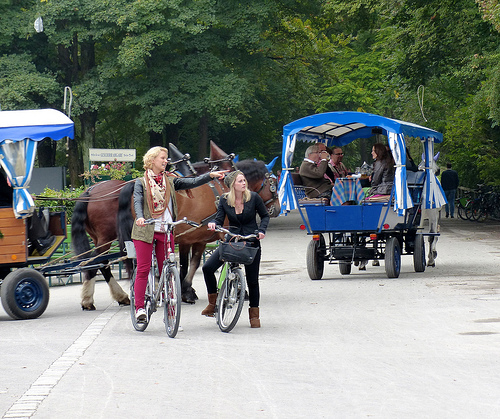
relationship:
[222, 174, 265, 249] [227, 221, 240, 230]
woman wearing black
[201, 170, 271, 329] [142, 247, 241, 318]
woman on bikes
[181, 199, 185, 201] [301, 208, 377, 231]
horse pulling carriage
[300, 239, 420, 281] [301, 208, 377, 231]
wheels of carriage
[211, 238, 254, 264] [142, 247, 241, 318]
basket on bikes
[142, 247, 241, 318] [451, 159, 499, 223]
bikes attached to railing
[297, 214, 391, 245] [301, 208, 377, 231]
reflectors on carriage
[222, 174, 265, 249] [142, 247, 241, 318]
woman on bikes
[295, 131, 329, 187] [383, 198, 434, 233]
man on wagon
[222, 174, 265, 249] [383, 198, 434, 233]
woman riding wagon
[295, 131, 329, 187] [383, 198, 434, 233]
man riding in wagon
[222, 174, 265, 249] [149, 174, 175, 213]
woman wearing scarf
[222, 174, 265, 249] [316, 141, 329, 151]
woman wearing hat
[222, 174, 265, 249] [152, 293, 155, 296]
woman wearing pants